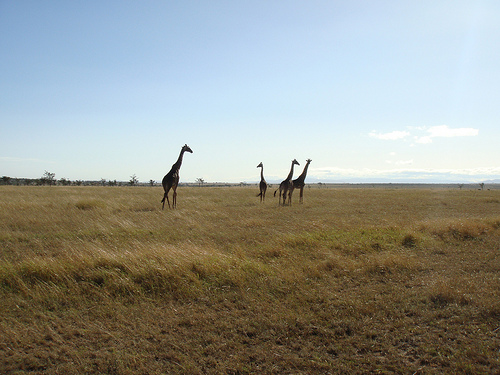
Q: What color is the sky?
A: Light Blue.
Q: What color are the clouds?
A: White.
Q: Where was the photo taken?
A: In the wild.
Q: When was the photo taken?
A: Daytime.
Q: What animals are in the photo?
A: Giraffes.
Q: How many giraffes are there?
A: Four.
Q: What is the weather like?
A: Sunny.